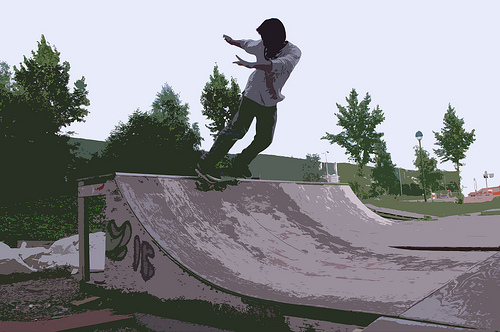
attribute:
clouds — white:
[88, 7, 127, 44]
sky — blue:
[82, 5, 205, 74]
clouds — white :
[411, 62, 483, 97]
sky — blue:
[43, 7, 219, 73]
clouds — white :
[0, 2, 497, 197]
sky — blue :
[7, 0, 487, 183]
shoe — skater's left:
[223, 150, 274, 177]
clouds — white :
[7, 0, 497, 97]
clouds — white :
[312, 17, 365, 49]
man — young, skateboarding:
[191, 13, 302, 178]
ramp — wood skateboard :
[72, 165, 498, 330]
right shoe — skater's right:
[176, 153, 251, 194]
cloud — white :
[132, 27, 212, 79]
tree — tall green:
[434, 93, 488, 198]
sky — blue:
[8, 3, 497, 123]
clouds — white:
[370, 17, 424, 82]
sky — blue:
[4, 5, 496, 172]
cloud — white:
[61, 37, 138, 94]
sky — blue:
[7, 9, 498, 204]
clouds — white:
[399, 29, 444, 59]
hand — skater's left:
[226, 51, 262, 73]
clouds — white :
[301, 1, 494, 89]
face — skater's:
[253, 31, 282, 56]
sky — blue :
[370, 10, 482, 68]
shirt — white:
[228, 37, 300, 104]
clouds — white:
[369, 32, 392, 74]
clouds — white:
[452, 97, 487, 129]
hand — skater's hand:
[221, 26, 238, 50]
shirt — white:
[236, 37, 301, 107]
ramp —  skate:
[154, 175, 467, 328]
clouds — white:
[329, 17, 425, 79]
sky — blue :
[378, 17, 439, 78]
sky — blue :
[397, 29, 457, 66]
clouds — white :
[346, 17, 426, 53]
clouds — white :
[393, 27, 446, 95]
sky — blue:
[399, 16, 462, 90]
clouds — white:
[350, 11, 461, 102]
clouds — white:
[338, 18, 463, 88]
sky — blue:
[108, 4, 208, 73]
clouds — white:
[361, 23, 487, 94]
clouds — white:
[392, 22, 481, 100]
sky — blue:
[349, 14, 426, 109]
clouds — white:
[341, 34, 426, 74]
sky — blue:
[334, 19, 448, 73]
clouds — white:
[308, 17, 428, 87]